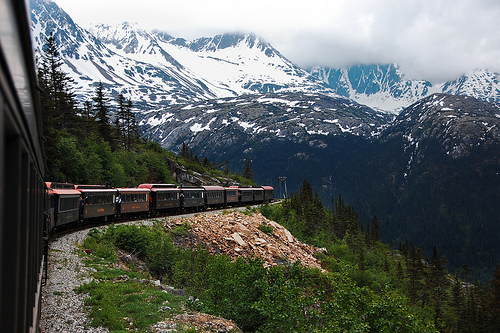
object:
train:
[51, 180, 274, 229]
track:
[41, 200, 276, 238]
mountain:
[26, 1, 496, 237]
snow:
[14, 0, 500, 150]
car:
[79, 185, 120, 224]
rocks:
[165, 205, 327, 277]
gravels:
[47, 228, 88, 331]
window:
[119, 194, 127, 202]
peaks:
[23, 0, 271, 61]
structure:
[277, 170, 289, 203]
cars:
[114, 189, 150, 218]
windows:
[86, 195, 116, 204]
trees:
[34, 62, 269, 188]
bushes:
[40, 116, 250, 188]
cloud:
[43, 0, 497, 90]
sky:
[22, 2, 499, 80]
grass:
[80, 224, 190, 333]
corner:
[145, 183, 155, 203]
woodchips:
[174, 209, 300, 264]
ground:
[143, 211, 342, 270]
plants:
[82, 182, 458, 331]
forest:
[27, 40, 235, 184]